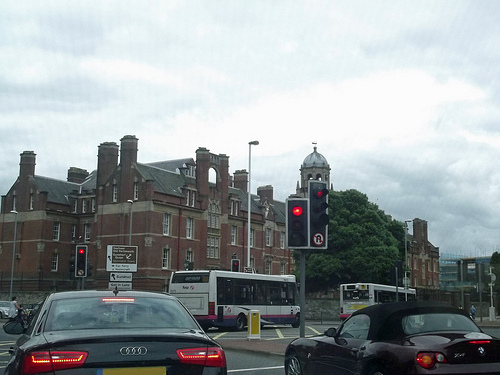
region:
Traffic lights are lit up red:
[282, 178, 331, 251]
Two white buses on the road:
[165, 263, 422, 329]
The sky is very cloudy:
[2, 4, 499, 258]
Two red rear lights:
[18, 340, 230, 373]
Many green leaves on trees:
[297, 186, 406, 286]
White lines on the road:
[209, 322, 324, 373]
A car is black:
[280, 297, 499, 373]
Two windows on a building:
[158, 207, 200, 243]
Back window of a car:
[40, 294, 203, 335]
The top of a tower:
[293, 141, 336, 183]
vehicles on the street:
[8, 263, 444, 355]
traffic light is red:
[278, 193, 323, 253]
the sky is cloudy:
[207, 60, 392, 159]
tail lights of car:
[2, 335, 214, 362]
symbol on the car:
[103, 345, 152, 367]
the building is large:
[11, 144, 249, 254]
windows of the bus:
[206, 268, 298, 303]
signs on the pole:
[85, 219, 142, 288]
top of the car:
[372, 293, 462, 331]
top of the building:
[298, 145, 325, 169]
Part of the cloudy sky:
[88, 27, 188, 80]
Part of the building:
[138, 214, 154, 231]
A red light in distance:
[76, 246, 84, 257]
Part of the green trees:
[351, 222, 375, 258]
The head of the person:
[8, 294, 19, 304]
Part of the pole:
[301, 282, 306, 306]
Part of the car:
[318, 347, 345, 362]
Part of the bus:
[178, 289, 203, 300]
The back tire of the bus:
[232, 311, 248, 331]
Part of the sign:
[316, 235, 323, 244]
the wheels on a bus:
[216, 299, 258, 336]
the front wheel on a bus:
[285, 293, 321, 333]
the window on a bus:
[211, 262, 306, 307]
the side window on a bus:
[213, 270, 300, 310]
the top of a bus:
[200, 251, 298, 296]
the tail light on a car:
[161, 315, 238, 372]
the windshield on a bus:
[51, 267, 193, 341]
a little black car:
[39, 242, 216, 362]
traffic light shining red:
[286, 192, 312, 249]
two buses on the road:
[160, 251, 439, 329]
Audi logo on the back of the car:
[111, 340, 155, 359]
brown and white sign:
[101, 240, 145, 274]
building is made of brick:
[0, 120, 308, 294]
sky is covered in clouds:
[1, 2, 496, 266]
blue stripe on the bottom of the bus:
[191, 306, 307, 328]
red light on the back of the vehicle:
[175, 341, 225, 368]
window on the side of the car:
[330, 309, 365, 339]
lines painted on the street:
[201, 318, 331, 342]